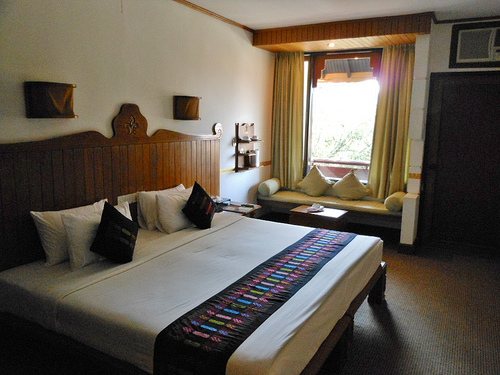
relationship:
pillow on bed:
[34, 198, 110, 269] [1, 103, 387, 374]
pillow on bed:
[61, 200, 136, 268] [1, 103, 387, 374]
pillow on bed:
[137, 180, 187, 234] [1, 103, 387, 374]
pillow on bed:
[184, 181, 215, 225] [1, 103, 387, 374]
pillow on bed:
[91, 202, 137, 265] [1, 103, 387, 374]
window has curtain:
[308, 51, 381, 181] [270, 43, 415, 201]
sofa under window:
[255, 173, 409, 229] [308, 51, 381, 181]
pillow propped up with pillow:
[91, 202, 137, 265] [184, 181, 215, 225]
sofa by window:
[255, 173, 409, 229] [308, 51, 381, 181]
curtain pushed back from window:
[270, 43, 415, 201] [308, 51, 381, 181]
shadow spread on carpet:
[316, 318, 410, 374] [249, 210, 495, 374]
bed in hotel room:
[1, 103, 387, 374] [1, 2, 500, 373]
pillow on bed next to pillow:
[34, 198, 110, 269] [137, 180, 187, 234]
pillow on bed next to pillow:
[91, 202, 137, 265] [184, 181, 215, 225]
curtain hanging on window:
[270, 43, 415, 201] [308, 51, 381, 181]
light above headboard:
[23, 79, 77, 118] [1, 103, 221, 273]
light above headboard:
[171, 94, 202, 120] [1, 103, 221, 273]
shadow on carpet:
[316, 318, 410, 374] [249, 210, 495, 374]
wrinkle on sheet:
[154, 294, 193, 324] [2, 182, 384, 374]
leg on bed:
[370, 269, 392, 301] [1, 103, 387, 374]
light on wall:
[23, 79, 77, 118] [1, 1, 276, 223]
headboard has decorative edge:
[1, 103, 221, 273] [110, 103, 145, 136]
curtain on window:
[270, 43, 415, 201] [308, 51, 381, 181]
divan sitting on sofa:
[258, 177, 283, 197] [255, 173, 409, 229]